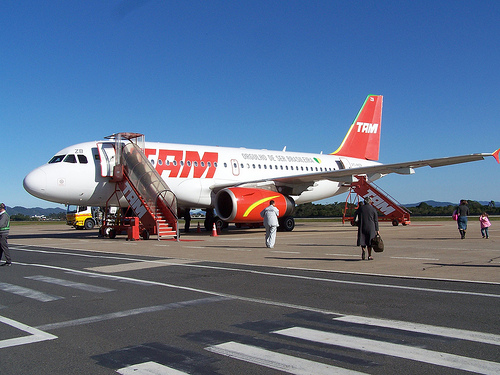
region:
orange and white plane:
[23, 90, 433, 231]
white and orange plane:
[21, 81, 483, 234]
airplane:
[10, 100, 484, 214]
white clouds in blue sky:
[32, 29, 91, 84]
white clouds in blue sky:
[180, 43, 222, 92]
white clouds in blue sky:
[420, 34, 465, 63]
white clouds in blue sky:
[197, 54, 272, 122]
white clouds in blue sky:
[229, 63, 284, 134]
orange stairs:
[103, 142, 187, 243]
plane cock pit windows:
[44, 148, 86, 171]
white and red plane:
[23, 88, 495, 233]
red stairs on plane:
[113, 141, 181, 240]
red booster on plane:
[216, 187, 286, 224]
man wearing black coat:
[353, 193, 381, 255]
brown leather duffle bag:
[373, 232, 385, 253]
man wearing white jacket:
[261, 198, 280, 246]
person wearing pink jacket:
[478, 211, 490, 239]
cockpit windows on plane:
[50, 153, 87, 163]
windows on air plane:
[149, 156, 345, 174]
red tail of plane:
[336, 92, 384, 162]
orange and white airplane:
[28, 73, 473, 215]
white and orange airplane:
[22, 97, 466, 226]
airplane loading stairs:
[109, 139, 181, 239]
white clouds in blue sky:
[22, 21, 84, 63]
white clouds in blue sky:
[146, 65, 181, 109]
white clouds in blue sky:
[223, 33, 263, 91]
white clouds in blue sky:
[422, 51, 484, 86]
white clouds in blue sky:
[267, 3, 309, 58]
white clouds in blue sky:
[153, 54, 221, 100]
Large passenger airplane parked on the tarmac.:
[22, 94, 498, 242]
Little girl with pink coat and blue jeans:
[477, 211, 491, 241]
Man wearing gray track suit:
[258, 198, 282, 250]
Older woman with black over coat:
[347, 193, 385, 261]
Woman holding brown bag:
[370, 230, 389, 255]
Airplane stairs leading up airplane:
[118, 142, 185, 239]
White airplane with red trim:
[24, 88, 494, 226]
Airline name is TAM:
[354, 119, 381, 138]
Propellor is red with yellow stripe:
[212, 187, 294, 222]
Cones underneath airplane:
[190, 217, 220, 240]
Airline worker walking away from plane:
[1, 202, 16, 267]